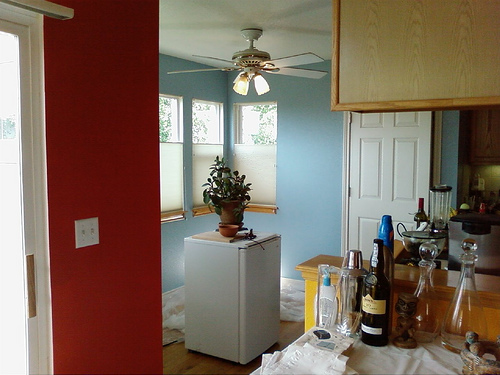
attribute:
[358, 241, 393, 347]
bottle — here, brown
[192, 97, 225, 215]
window — here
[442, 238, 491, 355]
glass — here, tall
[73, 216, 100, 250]
switch — white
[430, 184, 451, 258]
blender — here, black, clear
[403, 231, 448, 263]
bowl — empty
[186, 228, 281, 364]
fridge — small, here, white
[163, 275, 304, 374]
floor — wooden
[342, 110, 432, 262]
door — closed, white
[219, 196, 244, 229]
planter — brown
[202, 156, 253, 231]
plant — here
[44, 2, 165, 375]
wall — red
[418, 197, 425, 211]
top — red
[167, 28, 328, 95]
fan — here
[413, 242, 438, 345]
bottle — clear